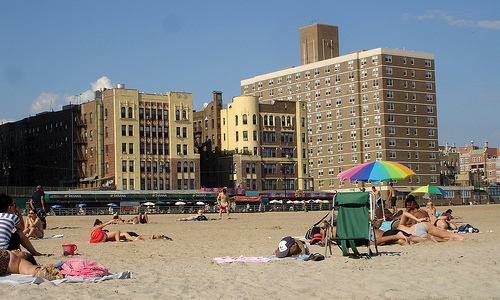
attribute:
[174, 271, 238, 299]
sand — white, white colored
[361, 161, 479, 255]
family — together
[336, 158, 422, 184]
umbrella — colored, rainbow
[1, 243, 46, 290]
woman — sunbather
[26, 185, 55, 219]
man — wearing jeans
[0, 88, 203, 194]
building — tall, brown, older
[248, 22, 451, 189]
apartment — hi-rise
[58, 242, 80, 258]
pail — red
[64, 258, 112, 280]
blanket — small, pink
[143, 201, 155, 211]
umbrella — white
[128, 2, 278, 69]
sky — blue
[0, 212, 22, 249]
shirt — striped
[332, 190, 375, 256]
chair — green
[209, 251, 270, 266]
towel — pink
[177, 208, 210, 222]
person — laying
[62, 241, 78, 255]
bucket — red